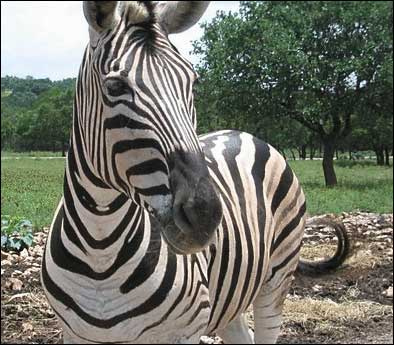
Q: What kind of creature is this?
A: Zebra.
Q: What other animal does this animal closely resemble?
A: Horse.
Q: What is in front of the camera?
A: Zebra.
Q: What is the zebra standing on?
A: Dirt.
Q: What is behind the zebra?
A: Dirt and grass.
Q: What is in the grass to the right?
A: Tree.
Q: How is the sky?
A: Partly cloudy.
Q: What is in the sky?
A: Clouds.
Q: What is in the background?
A: Trees.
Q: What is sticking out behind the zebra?
A: Tail.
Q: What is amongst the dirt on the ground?
A: Straw.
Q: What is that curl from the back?
A: A tail.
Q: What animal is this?
A: A zebra.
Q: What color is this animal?
A: Black and white.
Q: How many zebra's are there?
A: One.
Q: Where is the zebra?
A: In a field.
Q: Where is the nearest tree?
A: Behind the zebra.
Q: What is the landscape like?
A: Heavily treed.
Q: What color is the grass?
A: Green.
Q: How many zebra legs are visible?
A: Two.